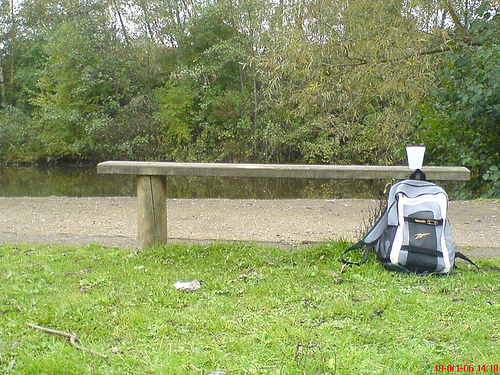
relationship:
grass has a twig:
[10, 246, 493, 372] [23, 322, 111, 364]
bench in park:
[95, 153, 473, 256] [5, 12, 489, 367]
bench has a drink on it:
[95, 153, 473, 256] [405, 145, 427, 170]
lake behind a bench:
[4, 155, 487, 201] [95, 153, 473, 256]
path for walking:
[5, 192, 497, 259] [3, 192, 499, 261]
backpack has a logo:
[340, 169, 476, 277] [414, 231, 433, 245]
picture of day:
[5, 7, 492, 371] [19, 1, 461, 82]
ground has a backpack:
[10, 246, 493, 372] [340, 169, 476, 277]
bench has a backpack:
[95, 153, 473, 256] [340, 169, 476, 277]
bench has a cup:
[95, 153, 473, 256] [405, 145, 427, 170]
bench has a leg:
[95, 153, 473, 256] [133, 174, 172, 261]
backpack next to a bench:
[340, 169, 476, 277] [95, 153, 473, 256]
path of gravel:
[5, 192, 497, 259] [75, 209, 112, 227]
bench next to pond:
[95, 153, 473, 256] [4, 155, 487, 201]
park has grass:
[5, 12, 489, 367] [10, 246, 493, 372]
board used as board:
[94, 156, 471, 186] [94, 160, 471, 183]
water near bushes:
[4, 155, 487, 201] [356, 19, 491, 173]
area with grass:
[9, 29, 490, 375] [10, 246, 493, 372]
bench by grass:
[95, 153, 473, 256] [10, 246, 493, 372]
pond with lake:
[4, 155, 487, 201] [0, 155, 487, 201]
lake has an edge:
[0, 155, 487, 201] [4, 186, 371, 210]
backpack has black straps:
[340, 169, 476, 277] [341, 188, 365, 265]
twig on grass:
[14, 301, 122, 364] [10, 246, 493, 372]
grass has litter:
[10, 246, 493, 372] [167, 279, 202, 292]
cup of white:
[406, 145, 430, 172] [408, 151, 416, 159]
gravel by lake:
[75, 209, 112, 227] [0, 155, 487, 201]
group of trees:
[6, 10, 478, 167] [13, 9, 255, 151]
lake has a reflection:
[0, 155, 487, 201] [44, 170, 93, 187]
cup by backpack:
[406, 145, 430, 172] [340, 169, 476, 277]